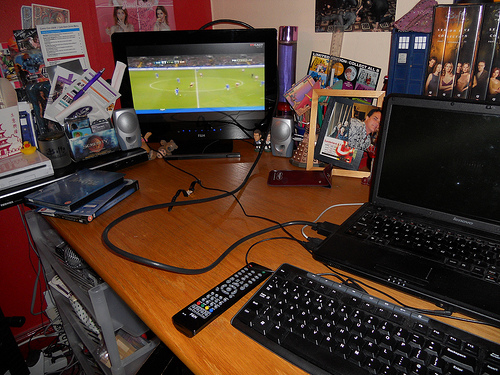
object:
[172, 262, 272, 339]
remote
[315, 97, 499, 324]
laptop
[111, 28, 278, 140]
monitor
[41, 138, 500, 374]
desktop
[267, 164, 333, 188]
case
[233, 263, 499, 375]
keyboard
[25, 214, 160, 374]
bin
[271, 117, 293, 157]
speakers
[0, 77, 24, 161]
container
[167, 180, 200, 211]
wristwatch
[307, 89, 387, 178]
frame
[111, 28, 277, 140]
computer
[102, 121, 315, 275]
black cord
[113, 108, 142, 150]
speaker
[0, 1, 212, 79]
wall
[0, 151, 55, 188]
dvd player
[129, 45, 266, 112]
soccer game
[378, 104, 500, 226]
screen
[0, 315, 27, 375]
chair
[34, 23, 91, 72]
messy papers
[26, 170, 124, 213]
dvd's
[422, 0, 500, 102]
collection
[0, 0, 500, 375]
room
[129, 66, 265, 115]
field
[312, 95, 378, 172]
pictures